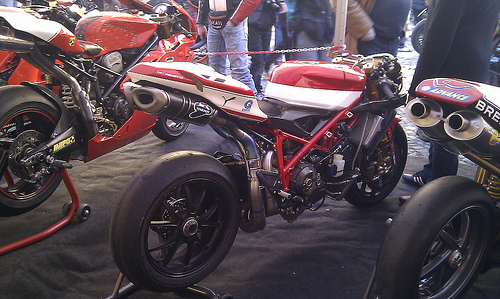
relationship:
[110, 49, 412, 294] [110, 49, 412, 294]
bikes a red bikes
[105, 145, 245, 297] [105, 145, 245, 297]
wheel a wheel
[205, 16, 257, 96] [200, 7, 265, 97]
jeans are his blue jeans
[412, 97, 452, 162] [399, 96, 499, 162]
these are two pipes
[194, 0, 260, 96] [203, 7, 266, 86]
man wearing jeans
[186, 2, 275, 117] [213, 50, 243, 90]
man has his hand in pocket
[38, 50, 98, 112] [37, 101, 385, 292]
handle on motorcycle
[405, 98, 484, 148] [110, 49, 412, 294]
muffler on back of bikes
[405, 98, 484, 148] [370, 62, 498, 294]
muffler on back of motorcycle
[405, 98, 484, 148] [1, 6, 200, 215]
muffler on back of motorcycle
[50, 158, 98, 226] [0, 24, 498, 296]
stand on floor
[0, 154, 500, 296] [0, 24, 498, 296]
covering on floor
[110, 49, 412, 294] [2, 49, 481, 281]
bikes that are inside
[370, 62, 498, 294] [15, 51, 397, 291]
motorcycle that are on display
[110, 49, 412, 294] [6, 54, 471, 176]
bikes are red and white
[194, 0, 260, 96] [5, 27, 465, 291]
man near motorcycles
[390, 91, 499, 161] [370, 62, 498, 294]
pipes on motorcycle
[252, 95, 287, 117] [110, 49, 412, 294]
seat on bikes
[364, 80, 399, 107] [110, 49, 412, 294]
handle motorcycle on bikes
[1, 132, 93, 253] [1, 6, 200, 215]
clamp on motorcycle